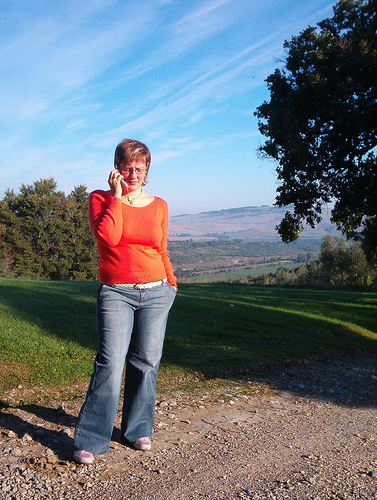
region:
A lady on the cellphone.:
[73, 130, 167, 228]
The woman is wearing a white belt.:
[98, 272, 156, 292]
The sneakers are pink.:
[67, 428, 157, 450]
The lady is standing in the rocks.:
[70, 138, 168, 416]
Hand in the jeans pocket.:
[150, 242, 179, 290]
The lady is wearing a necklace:
[121, 187, 145, 204]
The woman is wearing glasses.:
[104, 164, 155, 177]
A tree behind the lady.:
[16, 182, 101, 272]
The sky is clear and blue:
[69, 54, 272, 158]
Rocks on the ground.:
[171, 383, 350, 443]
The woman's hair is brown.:
[104, 137, 151, 193]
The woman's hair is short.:
[111, 136, 151, 192]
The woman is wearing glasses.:
[112, 138, 151, 191]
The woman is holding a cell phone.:
[110, 134, 151, 187]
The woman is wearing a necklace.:
[111, 135, 153, 203]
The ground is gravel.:
[238, 452, 329, 499]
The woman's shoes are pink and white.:
[68, 437, 164, 462]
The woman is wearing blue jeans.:
[74, 276, 175, 448]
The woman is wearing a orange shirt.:
[86, 187, 180, 288]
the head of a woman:
[106, 153, 162, 202]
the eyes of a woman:
[113, 159, 158, 182]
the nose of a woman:
[119, 168, 141, 189]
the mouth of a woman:
[123, 175, 144, 192]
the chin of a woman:
[110, 178, 154, 210]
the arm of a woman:
[75, 168, 148, 257]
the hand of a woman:
[103, 156, 146, 206]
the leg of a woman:
[81, 278, 222, 439]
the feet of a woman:
[67, 404, 182, 478]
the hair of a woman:
[106, 153, 157, 178]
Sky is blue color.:
[70, 35, 213, 121]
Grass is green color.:
[198, 297, 319, 363]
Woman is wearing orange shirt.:
[78, 132, 177, 293]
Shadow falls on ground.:
[15, 272, 342, 462]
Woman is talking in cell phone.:
[104, 139, 154, 203]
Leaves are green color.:
[276, 11, 363, 197]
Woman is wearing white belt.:
[98, 263, 177, 305]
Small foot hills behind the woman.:
[59, 141, 364, 281]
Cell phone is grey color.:
[107, 167, 130, 199]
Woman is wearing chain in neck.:
[98, 138, 164, 223]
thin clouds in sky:
[1, 1, 332, 216]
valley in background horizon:
[170, 205, 329, 282]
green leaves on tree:
[0, 178, 88, 277]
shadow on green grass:
[2, 284, 374, 370]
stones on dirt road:
[1, 382, 375, 496]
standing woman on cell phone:
[74, 138, 179, 461]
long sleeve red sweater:
[88, 188, 173, 286]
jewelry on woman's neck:
[127, 188, 143, 204]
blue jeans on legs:
[72, 283, 173, 450]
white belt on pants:
[114, 277, 168, 287]